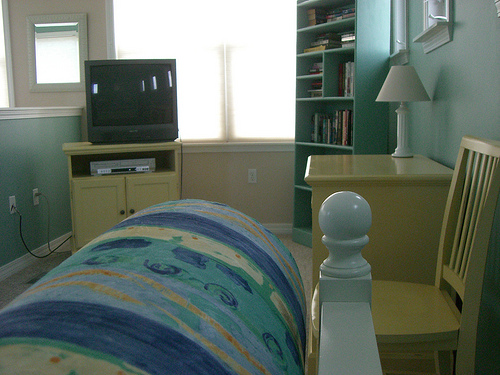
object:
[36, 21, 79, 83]
mirror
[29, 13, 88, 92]
frame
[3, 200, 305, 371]
blanket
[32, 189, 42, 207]
outlets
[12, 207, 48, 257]
wires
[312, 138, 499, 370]
chair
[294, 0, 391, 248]
bookcase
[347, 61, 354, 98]
books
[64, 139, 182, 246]
stand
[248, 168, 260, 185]
electrical outlet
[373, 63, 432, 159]
lamp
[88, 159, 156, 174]
dvd player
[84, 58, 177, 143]
television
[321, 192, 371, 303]
pole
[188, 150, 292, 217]
wall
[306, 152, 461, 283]
dresser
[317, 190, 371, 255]
knob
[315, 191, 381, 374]
bed post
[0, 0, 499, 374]
bedroom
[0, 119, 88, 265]
wall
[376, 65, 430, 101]
lampshade